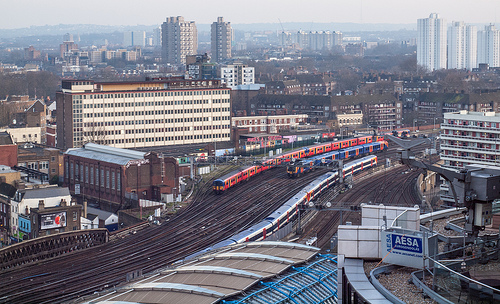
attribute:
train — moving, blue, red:
[293, 141, 390, 175]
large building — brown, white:
[55, 78, 232, 143]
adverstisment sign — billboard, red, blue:
[39, 211, 67, 231]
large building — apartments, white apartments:
[440, 110, 500, 169]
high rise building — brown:
[160, 16, 196, 72]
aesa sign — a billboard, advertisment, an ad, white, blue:
[382, 230, 429, 272]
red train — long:
[214, 135, 384, 189]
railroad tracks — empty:
[157, 195, 269, 240]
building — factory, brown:
[67, 151, 181, 202]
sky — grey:
[1, 0, 500, 23]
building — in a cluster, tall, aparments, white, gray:
[417, 19, 447, 72]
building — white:
[447, 26, 476, 70]